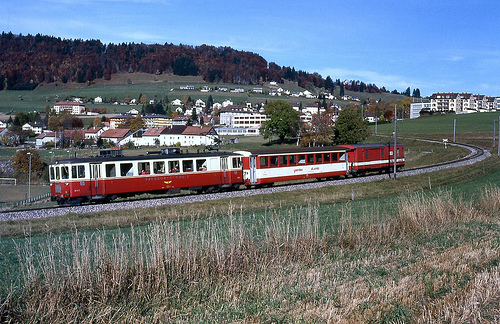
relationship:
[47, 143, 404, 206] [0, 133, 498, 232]
train on train tracks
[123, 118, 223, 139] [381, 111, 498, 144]
house on hill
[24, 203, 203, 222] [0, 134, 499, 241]
gravel next to tracks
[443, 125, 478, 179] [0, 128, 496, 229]
rails on track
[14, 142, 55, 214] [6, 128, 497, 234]
poles next to tracks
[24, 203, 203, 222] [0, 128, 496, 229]
gravel next to track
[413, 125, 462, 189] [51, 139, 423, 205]
track behind train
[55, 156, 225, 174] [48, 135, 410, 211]
windows in train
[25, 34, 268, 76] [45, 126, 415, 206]
trees are behind train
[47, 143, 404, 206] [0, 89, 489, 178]
train travelling thru city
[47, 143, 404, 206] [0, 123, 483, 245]
train on track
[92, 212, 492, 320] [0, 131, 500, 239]
rockd around track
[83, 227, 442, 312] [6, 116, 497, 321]
grass in field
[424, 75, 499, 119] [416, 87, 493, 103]
buildings has roof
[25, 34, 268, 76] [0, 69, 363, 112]
trees are on hills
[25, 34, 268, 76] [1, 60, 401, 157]
trees are on village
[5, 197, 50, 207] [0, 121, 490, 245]
fence close to traint racks